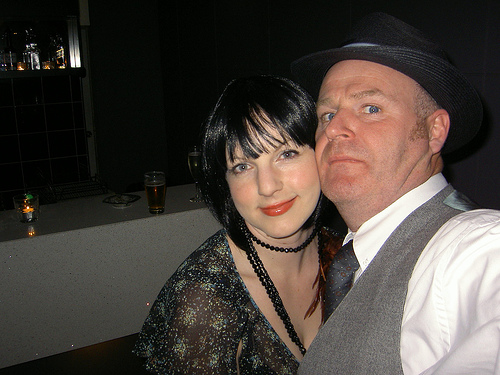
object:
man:
[297, 25, 500, 374]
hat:
[287, 10, 483, 163]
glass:
[141, 173, 169, 214]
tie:
[323, 238, 361, 323]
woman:
[131, 73, 361, 374]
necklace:
[239, 221, 319, 356]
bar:
[0, 182, 224, 367]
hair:
[199, 74, 319, 253]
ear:
[423, 107, 451, 155]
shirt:
[135, 226, 359, 374]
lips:
[258, 194, 299, 216]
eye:
[358, 104, 382, 116]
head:
[314, 33, 451, 201]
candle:
[18, 198, 38, 222]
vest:
[295, 182, 476, 374]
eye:
[317, 110, 336, 122]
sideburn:
[408, 114, 429, 141]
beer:
[145, 183, 168, 210]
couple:
[130, 10, 500, 374]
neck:
[339, 171, 456, 239]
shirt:
[341, 170, 499, 374]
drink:
[186, 153, 205, 180]